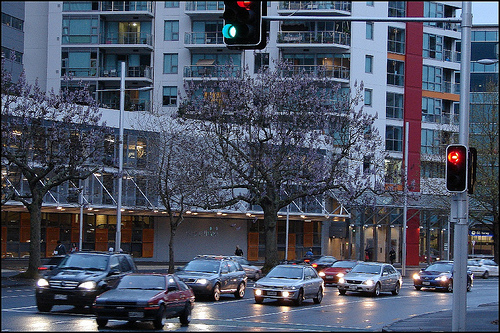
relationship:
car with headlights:
[336, 261, 402, 298] [335, 273, 375, 288]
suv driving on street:
[26, 245, 145, 310] [0, 260, 498, 327]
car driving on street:
[91, 273, 196, 330] [2, 253, 498, 331]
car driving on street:
[336, 261, 402, 298] [302, 275, 434, 307]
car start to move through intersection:
[252, 263, 326, 305] [5, 5, 492, 330]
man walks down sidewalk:
[233, 242, 242, 254] [141, 260, 179, 271]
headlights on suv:
[28, 274, 102, 293] [31, 246, 138, 311]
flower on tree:
[84, 95, 94, 105] [0, 42, 135, 282]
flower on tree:
[33, 77, 42, 94] [0, 42, 135, 282]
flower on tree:
[94, 111, 102, 122] [0, 42, 135, 282]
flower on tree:
[22, 80, 36, 95] [0, 42, 135, 282]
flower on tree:
[60, 112, 74, 125] [0, 42, 135, 282]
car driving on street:
[168, 252, 248, 301] [1, 273, 498, 330]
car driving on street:
[299, 205, 399, 330] [92, 284, 498, 329]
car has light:
[94, 269, 195, 328] [132, 300, 149, 310]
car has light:
[94, 269, 195, 328] [95, 296, 112, 307]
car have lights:
[252, 263, 326, 305] [334, 274, 379, 289]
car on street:
[252, 263, 326, 305] [18, 275, 489, 328]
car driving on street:
[318, 259, 361, 281] [3, 279, 498, 330]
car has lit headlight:
[249, 261, 326, 309] [281, 288, 290, 299]